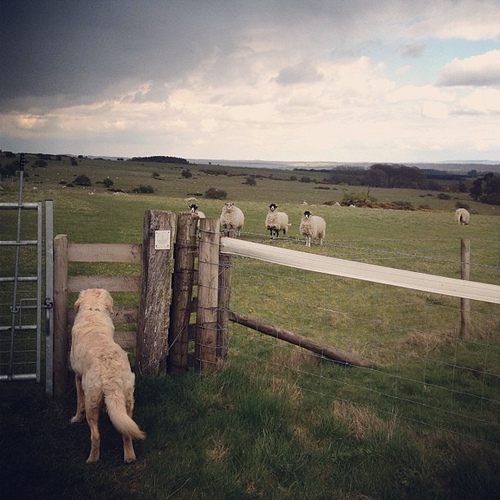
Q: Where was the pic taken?
A: In the field.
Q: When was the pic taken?
A: During the day.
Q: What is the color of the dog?
A: White.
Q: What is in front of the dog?
A: A fence.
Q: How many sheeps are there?
A: 4.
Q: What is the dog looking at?
A: Sheep.